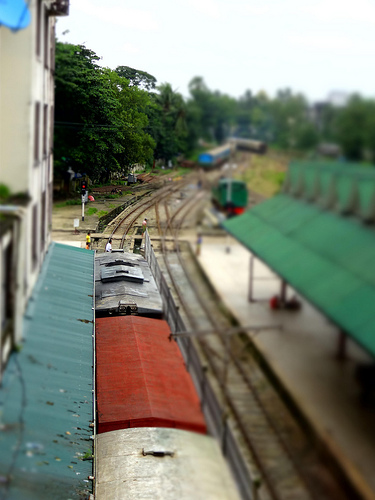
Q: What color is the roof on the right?
A: Green.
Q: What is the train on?
A: Train track.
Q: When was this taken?
A: Daytime.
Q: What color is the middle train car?
A: Red.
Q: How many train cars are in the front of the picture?
A: Three.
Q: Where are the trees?
A: Background.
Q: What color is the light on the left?
A: Red.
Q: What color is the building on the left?
A: White.